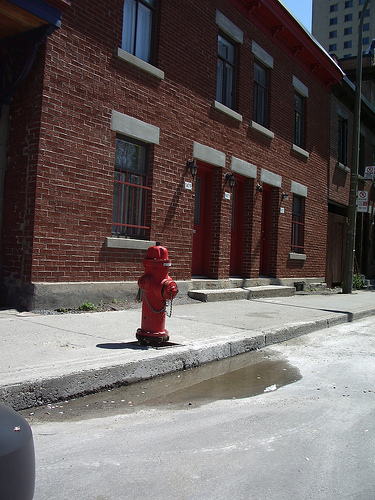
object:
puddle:
[21, 345, 302, 424]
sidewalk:
[0, 290, 373, 409]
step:
[0, 305, 375, 409]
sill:
[116, 47, 167, 81]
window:
[120, 76, 157, 142]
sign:
[184, 181, 194, 191]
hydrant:
[135, 243, 176, 347]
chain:
[143, 295, 166, 313]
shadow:
[245, 285, 348, 314]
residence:
[0, 0, 372, 308]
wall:
[30, 0, 372, 284]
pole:
[339, 2, 366, 292]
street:
[0, 300, 375, 494]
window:
[112, 136, 148, 238]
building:
[312, 2, 374, 57]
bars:
[121, 174, 127, 235]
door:
[192, 160, 220, 275]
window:
[194, 182, 202, 222]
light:
[191, 160, 200, 171]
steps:
[188, 287, 296, 302]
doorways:
[261, 173, 282, 281]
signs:
[356, 188, 367, 208]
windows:
[328, 42, 338, 51]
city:
[2, 3, 375, 498]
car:
[0, 404, 33, 500]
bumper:
[0, 404, 37, 500]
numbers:
[185, 181, 192, 189]